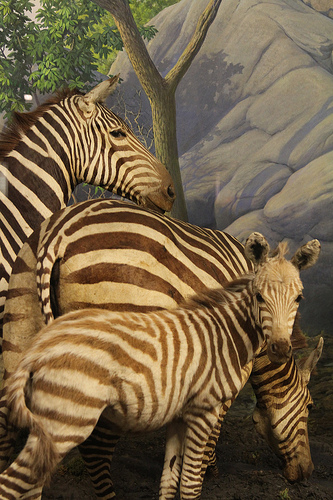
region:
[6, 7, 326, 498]
a scene at a zoo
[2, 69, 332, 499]
a group of zebras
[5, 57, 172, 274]
a black and white zebras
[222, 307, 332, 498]
a zebra eating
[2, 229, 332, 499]
a zebra looking towards the camera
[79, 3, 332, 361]
a painting of a mountain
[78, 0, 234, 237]
a painting of a tree trunk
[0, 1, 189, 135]
a painting of green leaves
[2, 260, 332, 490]
a dirt ground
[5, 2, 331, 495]
some animals here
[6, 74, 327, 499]
Three zebras are in the picture.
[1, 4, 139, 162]
The tree is next to the zebra.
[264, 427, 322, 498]
The zebra is eating grass.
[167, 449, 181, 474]
The zebra has a spot on its' leg.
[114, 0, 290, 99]
The tree is next to the rock.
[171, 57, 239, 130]
The tree's shadow is on the rock.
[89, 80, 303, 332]
Two zebras are looking up.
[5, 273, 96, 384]
The bottom tail is lighter than the top one.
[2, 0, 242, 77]
The trees and rocks are painted onto picture.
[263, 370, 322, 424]
Zebra is looking down.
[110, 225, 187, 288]
pattern on side of zebra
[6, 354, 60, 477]
small tail on zebra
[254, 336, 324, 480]
zebra grazing on grass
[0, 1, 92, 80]
trees with green leaves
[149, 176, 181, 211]
nose on large zebra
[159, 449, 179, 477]
black spot on leg of zebra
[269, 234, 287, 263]
white mane hair on zebra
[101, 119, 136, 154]
black eye on zebra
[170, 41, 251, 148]
shadow of tree on large rock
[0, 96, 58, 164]
long hair on back of zebra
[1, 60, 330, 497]
stuffed zebras in front of a painted backdrop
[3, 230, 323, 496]
the baby zebra is in the front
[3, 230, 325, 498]
baby zebra has shaggy hair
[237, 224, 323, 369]
baby zebra's ears look a little moth-eaten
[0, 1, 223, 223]
a fake painted tree behind the zebras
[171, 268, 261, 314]
stripes on zebra's neck extend up into the mane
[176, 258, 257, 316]
this fake zebra's mane is not stiff and upright like with a living zebra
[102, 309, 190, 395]
zebra's stripes fit together like an interlocking mosaic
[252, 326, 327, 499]
a zebra fake grazing at the fake grass in the display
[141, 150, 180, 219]
zebra has a dark snout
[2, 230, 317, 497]
baby zebra staring at the camera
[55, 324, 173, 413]
light colored baby zebra stripes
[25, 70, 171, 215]
adult zebra giving camera sidelong glance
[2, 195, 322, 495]
adult zebra grazing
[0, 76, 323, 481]
two adult zebras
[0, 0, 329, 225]
environment mural in the background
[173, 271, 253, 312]
baby zebra mane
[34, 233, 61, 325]
Zebra tail stripes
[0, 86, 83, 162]
Adult zebra mane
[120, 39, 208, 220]
tree painted on a wall